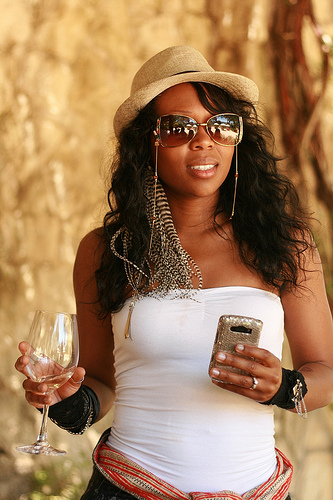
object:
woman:
[13, 42, 331, 500]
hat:
[110, 42, 260, 143]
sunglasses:
[150, 111, 244, 151]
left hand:
[209, 341, 284, 407]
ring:
[247, 374, 261, 392]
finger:
[207, 367, 276, 390]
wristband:
[262, 364, 309, 412]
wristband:
[38, 385, 100, 438]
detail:
[291, 375, 310, 419]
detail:
[59, 411, 93, 435]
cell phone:
[207, 313, 262, 387]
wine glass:
[14, 307, 82, 460]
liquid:
[34, 368, 74, 396]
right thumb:
[57, 362, 87, 397]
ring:
[68, 375, 86, 388]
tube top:
[104, 282, 287, 498]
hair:
[82, 81, 326, 327]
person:
[168, 123, 177, 139]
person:
[172, 126, 181, 137]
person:
[206, 123, 214, 136]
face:
[149, 83, 239, 199]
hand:
[13, 341, 88, 412]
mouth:
[185, 155, 221, 181]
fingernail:
[235, 343, 244, 350]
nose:
[187, 128, 217, 151]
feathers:
[107, 165, 204, 305]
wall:
[0, 0, 332, 498]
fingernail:
[209, 368, 221, 379]